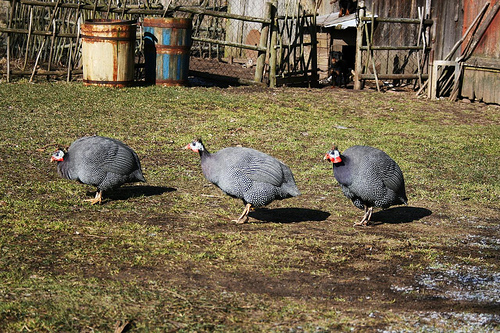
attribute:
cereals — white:
[384, 253, 495, 314]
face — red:
[319, 147, 340, 164]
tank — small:
[144, 18, 185, 87]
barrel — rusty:
[150, 16, 187, 71]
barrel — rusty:
[72, 12, 149, 97]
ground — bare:
[114, 248, 224, 303]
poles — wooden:
[238, 29, 290, 88]